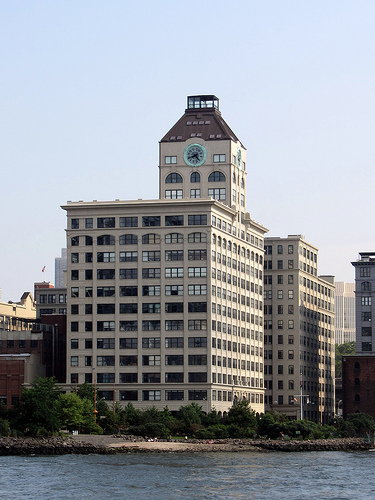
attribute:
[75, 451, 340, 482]
water — dark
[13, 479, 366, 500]
water — still blue  and clear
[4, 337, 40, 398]
building —  red  and brick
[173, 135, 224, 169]
clock —  circular and green 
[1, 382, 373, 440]
trees — green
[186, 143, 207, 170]
clock — green, black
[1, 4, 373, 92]
sky — clear, blue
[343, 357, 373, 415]
building — brown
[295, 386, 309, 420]
pole — tall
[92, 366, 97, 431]
pole — brown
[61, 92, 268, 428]
clock tower — building, identical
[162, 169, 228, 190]
circular windows — three